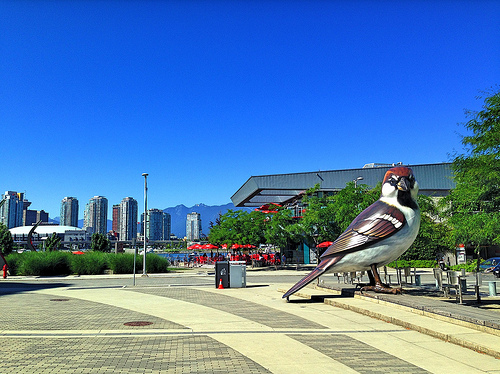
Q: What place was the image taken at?
A: It was taken at the walkway.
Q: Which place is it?
A: It is a walkway.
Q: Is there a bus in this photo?
A: No, there are no buses.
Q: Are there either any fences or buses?
A: No, there are no buses or fences.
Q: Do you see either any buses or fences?
A: No, there are no buses or fences.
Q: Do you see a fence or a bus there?
A: No, there are no buses or fences.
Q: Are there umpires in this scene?
A: No, there are no umpires.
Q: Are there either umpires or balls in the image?
A: No, there are no umpires or balls.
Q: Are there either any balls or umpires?
A: No, there are no umpires or balls.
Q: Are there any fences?
A: No, there are no fences.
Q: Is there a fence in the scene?
A: No, there are no fences.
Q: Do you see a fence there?
A: No, there are no fences.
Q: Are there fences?
A: No, there are no fences.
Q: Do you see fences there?
A: No, there are no fences.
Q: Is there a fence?
A: No, there are no fences.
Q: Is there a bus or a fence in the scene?
A: No, there are no fences or buses.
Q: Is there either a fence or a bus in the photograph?
A: No, there are no fences or buses.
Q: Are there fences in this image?
A: No, there are no fences.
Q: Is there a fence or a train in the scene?
A: No, there are no fences or trains.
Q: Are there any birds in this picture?
A: Yes, there is a bird.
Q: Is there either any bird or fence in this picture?
A: Yes, there is a bird.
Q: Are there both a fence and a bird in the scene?
A: No, there is a bird but no fences.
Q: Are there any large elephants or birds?
A: Yes, there is a large bird.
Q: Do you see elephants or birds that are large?
A: Yes, the bird is large.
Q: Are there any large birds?
A: Yes, there is a large bird.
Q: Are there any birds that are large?
A: Yes, there is a bird that is large.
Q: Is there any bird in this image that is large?
A: Yes, there is a bird that is large.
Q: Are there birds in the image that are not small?
A: Yes, there is a large bird.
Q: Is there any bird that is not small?
A: Yes, there is a large bird.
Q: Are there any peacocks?
A: No, there are no peacocks.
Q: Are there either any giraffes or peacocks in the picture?
A: No, there are no peacocks or giraffes.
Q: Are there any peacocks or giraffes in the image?
A: No, there are no peacocks or giraffes.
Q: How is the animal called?
A: The animal is a bird.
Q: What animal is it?
A: The animal is a bird.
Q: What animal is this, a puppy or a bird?
A: This is a bird.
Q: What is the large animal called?
A: The animal is a bird.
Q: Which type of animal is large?
A: The animal is a bird.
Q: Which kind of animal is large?
A: The animal is a bird.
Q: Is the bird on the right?
A: Yes, the bird is on the right of the image.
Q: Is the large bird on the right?
A: Yes, the bird is on the right of the image.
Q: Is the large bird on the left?
A: No, the bird is on the right of the image.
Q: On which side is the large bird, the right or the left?
A: The bird is on the right of the image.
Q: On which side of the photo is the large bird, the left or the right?
A: The bird is on the right of the image.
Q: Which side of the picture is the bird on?
A: The bird is on the right of the image.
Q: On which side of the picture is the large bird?
A: The bird is on the right of the image.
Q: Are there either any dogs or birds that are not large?
A: No, there is a bird but it is large.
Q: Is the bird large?
A: Yes, the bird is large.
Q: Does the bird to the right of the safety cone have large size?
A: Yes, the bird is large.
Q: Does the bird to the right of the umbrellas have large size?
A: Yes, the bird is large.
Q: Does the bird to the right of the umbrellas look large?
A: Yes, the bird is large.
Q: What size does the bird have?
A: The bird has large size.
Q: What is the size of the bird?
A: The bird is large.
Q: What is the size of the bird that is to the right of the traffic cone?
A: The bird is large.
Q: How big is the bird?
A: The bird is large.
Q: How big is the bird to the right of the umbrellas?
A: The bird is large.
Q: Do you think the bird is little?
A: No, the bird is large.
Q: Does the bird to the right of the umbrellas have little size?
A: No, the bird is large.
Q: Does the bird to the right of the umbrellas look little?
A: No, the bird is large.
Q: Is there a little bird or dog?
A: No, there is a bird but it is large.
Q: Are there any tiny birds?
A: No, there is a bird but it is large.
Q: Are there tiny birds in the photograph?
A: No, there is a bird but it is large.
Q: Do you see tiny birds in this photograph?
A: No, there is a bird but it is large.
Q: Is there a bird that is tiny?
A: No, there is a bird but it is large.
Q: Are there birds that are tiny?
A: No, there is a bird but it is large.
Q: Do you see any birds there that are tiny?
A: No, there is a bird but it is large.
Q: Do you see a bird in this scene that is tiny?
A: No, there is a bird but it is large.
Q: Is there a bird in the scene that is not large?
A: No, there is a bird but it is large.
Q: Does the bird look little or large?
A: The bird is large.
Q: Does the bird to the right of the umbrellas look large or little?
A: The bird is large.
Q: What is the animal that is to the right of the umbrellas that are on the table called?
A: The animal is a bird.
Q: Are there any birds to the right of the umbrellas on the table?
A: Yes, there is a bird to the right of the umbrellas.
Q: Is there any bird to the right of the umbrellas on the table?
A: Yes, there is a bird to the right of the umbrellas.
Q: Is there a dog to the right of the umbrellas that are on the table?
A: No, there is a bird to the right of the umbrellas.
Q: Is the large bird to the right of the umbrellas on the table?
A: Yes, the bird is to the right of the umbrellas.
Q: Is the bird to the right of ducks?
A: No, the bird is to the right of the umbrellas.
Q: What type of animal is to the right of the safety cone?
A: The animal is a bird.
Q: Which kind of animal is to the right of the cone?
A: The animal is a bird.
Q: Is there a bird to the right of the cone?
A: Yes, there is a bird to the right of the cone.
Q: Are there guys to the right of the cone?
A: No, there is a bird to the right of the cone.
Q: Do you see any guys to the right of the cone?
A: No, there is a bird to the right of the cone.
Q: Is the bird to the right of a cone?
A: Yes, the bird is to the right of a cone.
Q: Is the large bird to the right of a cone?
A: Yes, the bird is to the right of a cone.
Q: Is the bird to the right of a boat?
A: No, the bird is to the right of a cone.